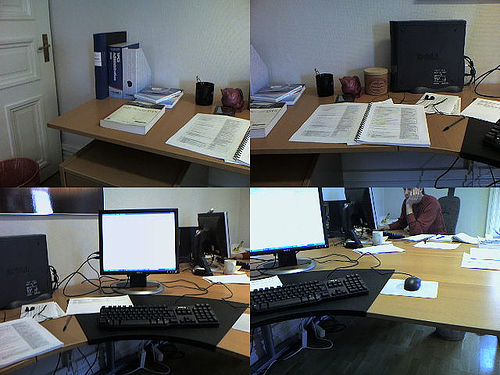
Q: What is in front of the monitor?
A: A keyboard.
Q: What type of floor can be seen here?
A: Hardwood floor.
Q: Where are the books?
A: On the table.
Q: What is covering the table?
A: Books and papers.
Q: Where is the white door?
A: Next to the desk.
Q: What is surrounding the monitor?
A: Wires.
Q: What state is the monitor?
A: Powered on.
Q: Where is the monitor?
A: Behind keyboard.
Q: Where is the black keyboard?
A: In front of the monitor.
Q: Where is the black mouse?
A: Next to the keyboard.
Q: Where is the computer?
A: On the table.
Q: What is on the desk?
A: Some books.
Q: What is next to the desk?
A: A door.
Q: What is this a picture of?
A: Office.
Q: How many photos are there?
A: Four.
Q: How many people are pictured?
A: One.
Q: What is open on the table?
A: Book.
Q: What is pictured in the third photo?
A: Computer.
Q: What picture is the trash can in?
A: First.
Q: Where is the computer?
A: On the desk.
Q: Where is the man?
A: At his desk.